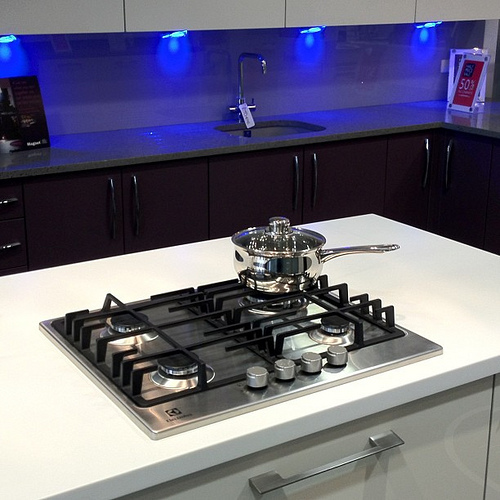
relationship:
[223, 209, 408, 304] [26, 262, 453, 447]
pan on stove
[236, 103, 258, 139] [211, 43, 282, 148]
pricetag on faucet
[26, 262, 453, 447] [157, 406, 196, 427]
stove has mark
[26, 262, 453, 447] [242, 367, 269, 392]
stove has knob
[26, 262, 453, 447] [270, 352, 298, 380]
stove has knob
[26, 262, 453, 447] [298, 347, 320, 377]
stove has knob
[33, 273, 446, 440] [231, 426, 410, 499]
stove has handle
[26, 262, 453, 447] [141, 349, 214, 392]
stove has burner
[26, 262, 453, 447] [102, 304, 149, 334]
stove has burner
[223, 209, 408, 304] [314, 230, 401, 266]
pan has handle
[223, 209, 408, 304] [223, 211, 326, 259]
pan has lid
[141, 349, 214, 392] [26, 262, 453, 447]
burner on stove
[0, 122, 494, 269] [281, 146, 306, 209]
cabinets have handle